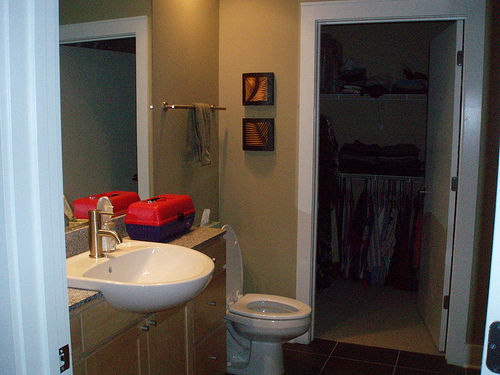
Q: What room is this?
A: It is a bathroom.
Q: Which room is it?
A: It is a bathroom.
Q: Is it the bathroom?
A: Yes, it is the bathroom.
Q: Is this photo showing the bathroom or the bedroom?
A: It is showing the bathroom.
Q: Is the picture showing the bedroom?
A: No, the picture is showing the bathroom.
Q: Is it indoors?
A: Yes, it is indoors.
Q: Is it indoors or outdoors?
A: It is indoors.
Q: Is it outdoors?
A: No, it is indoors.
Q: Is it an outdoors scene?
A: No, it is indoors.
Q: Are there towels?
A: Yes, there is a towel.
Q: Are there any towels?
A: Yes, there is a towel.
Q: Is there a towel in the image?
A: Yes, there is a towel.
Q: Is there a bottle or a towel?
A: Yes, there is a towel.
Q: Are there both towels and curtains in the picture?
A: No, there is a towel but no curtains.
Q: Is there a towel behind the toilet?
A: Yes, there is a towel behind the toilet.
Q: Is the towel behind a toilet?
A: Yes, the towel is behind a toilet.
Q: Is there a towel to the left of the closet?
A: Yes, there is a towel to the left of the closet.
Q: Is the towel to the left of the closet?
A: Yes, the towel is to the left of the closet.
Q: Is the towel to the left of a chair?
A: No, the towel is to the left of the closet.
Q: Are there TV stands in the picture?
A: No, there are no TV stands.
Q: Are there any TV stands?
A: No, there are no TV stands.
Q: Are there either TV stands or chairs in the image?
A: No, there are no TV stands or chairs.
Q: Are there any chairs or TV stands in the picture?
A: No, there are no TV stands or chairs.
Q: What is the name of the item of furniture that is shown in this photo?
A: The piece of furniture is a closet.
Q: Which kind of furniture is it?
A: The piece of furniture is a closet.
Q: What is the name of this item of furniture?
A: That is a closet.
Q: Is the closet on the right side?
A: Yes, the closet is on the right of the image.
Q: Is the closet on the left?
A: No, the closet is on the right of the image.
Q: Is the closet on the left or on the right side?
A: The closet is on the right of the image.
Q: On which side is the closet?
A: The closet is on the right of the image.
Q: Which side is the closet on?
A: The closet is on the right of the image.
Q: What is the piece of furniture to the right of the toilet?
A: The piece of furniture is a closet.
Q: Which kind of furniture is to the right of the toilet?
A: The piece of furniture is a closet.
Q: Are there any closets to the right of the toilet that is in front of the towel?
A: Yes, there is a closet to the right of the toilet.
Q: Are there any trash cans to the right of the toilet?
A: No, there is a closet to the right of the toilet.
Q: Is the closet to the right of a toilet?
A: Yes, the closet is to the right of a toilet.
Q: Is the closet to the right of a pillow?
A: No, the closet is to the right of a toilet.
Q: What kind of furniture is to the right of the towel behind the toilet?
A: The piece of furniture is a closet.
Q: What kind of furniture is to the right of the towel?
A: The piece of furniture is a closet.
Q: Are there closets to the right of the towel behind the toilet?
A: Yes, there is a closet to the right of the towel.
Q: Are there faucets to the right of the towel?
A: No, there is a closet to the right of the towel.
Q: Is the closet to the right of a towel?
A: Yes, the closet is to the right of a towel.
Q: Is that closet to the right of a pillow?
A: No, the closet is to the right of a towel.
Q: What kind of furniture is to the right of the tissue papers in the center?
A: The piece of furniture is a closet.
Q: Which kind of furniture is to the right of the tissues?
A: The piece of furniture is a closet.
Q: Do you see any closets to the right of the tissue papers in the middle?
A: Yes, there is a closet to the right of the tissue papers.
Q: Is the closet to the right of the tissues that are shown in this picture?
A: Yes, the closet is to the right of the tissues.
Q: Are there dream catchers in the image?
A: No, there are no dream catchers.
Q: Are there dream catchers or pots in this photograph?
A: No, there are no dream catchers or pots.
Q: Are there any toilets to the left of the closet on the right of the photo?
A: Yes, there is a toilet to the left of the closet.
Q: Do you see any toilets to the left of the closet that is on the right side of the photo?
A: Yes, there is a toilet to the left of the closet.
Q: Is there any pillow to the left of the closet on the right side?
A: No, there is a toilet to the left of the closet.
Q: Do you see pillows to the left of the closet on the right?
A: No, there is a toilet to the left of the closet.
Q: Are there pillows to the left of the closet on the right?
A: No, there is a toilet to the left of the closet.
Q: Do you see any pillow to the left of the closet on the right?
A: No, there is a toilet to the left of the closet.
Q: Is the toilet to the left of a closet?
A: Yes, the toilet is to the left of a closet.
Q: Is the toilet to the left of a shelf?
A: No, the toilet is to the left of a closet.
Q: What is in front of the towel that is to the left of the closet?
A: The toilet is in front of the towel.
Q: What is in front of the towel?
A: The toilet is in front of the towel.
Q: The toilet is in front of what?
A: The toilet is in front of the towel.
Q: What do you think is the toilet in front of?
A: The toilet is in front of the towel.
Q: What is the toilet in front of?
A: The toilet is in front of the towel.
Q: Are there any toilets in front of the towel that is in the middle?
A: Yes, there is a toilet in front of the towel.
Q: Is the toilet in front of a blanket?
A: No, the toilet is in front of the towel.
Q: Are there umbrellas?
A: No, there are no umbrellas.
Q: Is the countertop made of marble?
A: Yes, the countertop is made of marble.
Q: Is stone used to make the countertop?
A: No, the countertop is made of marble.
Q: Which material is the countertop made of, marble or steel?
A: The countertop is made of marble.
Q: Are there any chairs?
A: No, there are no chairs.